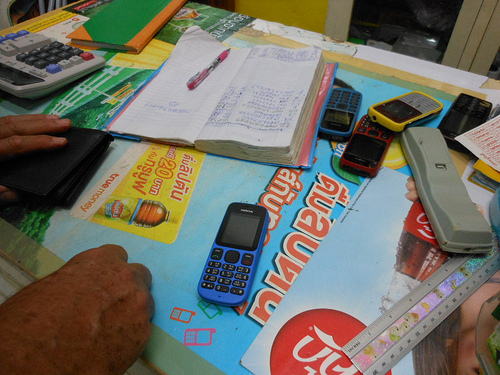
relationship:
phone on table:
[196, 198, 271, 305] [0, 0, 498, 373]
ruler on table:
[338, 227, 498, 374] [0, 0, 498, 373]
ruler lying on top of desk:
[340, 229, 500, 374] [83, 0, 493, 370]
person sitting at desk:
[0, 110, 161, 373] [2, 1, 483, 372]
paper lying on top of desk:
[451, 113, 483, 170] [2, 1, 483, 372]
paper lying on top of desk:
[106, 22, 250, 144] [2, 1, 483, 372]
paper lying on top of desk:
[195, 40, 325, 163] [2, 1, 483, 372]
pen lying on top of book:
[187, 42, 233, 94] [102, 22, 340, 171]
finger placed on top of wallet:
[2, 110, 61, 122] [10, 157, 84, 202]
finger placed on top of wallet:
[1, 116, 72, 134] [10, 157, 84, 202]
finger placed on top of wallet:
[2, 131, 67, 156] [10, 157, 84, 202]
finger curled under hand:
[104, 242, 126, 259] [2, 242, 157, 373]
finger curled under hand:
[131, 262, 150, 279] [2, 242, 157, 373]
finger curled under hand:
[149, 292, 155, 316] [2, 242, 157, 373]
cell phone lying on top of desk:
[314, 85, 363, 142] [2, 1, 483, 372]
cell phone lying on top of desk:
[337, 112, 395, 178] [2, 1, 483, 372]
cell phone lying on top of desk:
[367, 88, 444, 135] [2, 1, 483, 372]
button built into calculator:
[44, 62, 62, 73] [14, 18, 75, 102]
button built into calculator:
[56, 58, 74, 69] [14, 18, 75, 102]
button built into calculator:
[66, 52, 84, 65] [14, 18, 75, 102]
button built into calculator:
[32, 57, 50, 69] [14, 18, 75, 102]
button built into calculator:
[44, 52, 60, 62] [14, 18, 75, 102]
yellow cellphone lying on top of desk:
[359, 93, 448, 135] [2, 1, 483, 372]